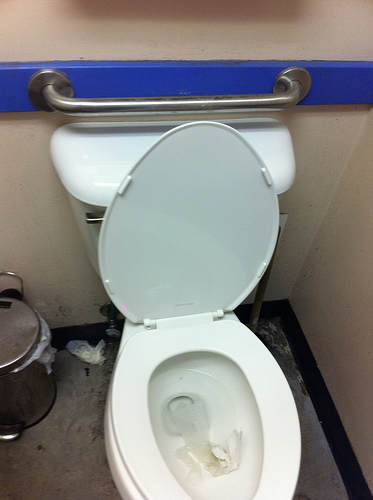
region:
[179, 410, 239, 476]
tissue in the toilet bowl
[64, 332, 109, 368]
paper on a dirty floor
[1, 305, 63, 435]
silver trash can near a toilet bowl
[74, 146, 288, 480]
toilet bowl with its seat up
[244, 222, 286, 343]
Plunger near a toilet bowl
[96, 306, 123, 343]
silver knob on the wall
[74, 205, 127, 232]
Chrome handle on a toilet bowl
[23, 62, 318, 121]
Hand bar over the towel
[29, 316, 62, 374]
Trash bag in a silver can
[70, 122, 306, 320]
white lid on a toilet seat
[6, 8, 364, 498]
a toilet is in a bathroom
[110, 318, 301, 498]
the seat is down on the toilet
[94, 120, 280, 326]
the lid of the toilet is up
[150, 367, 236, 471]
water is in the bowl of the toilet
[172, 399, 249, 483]
paper is in the bowl of the toilet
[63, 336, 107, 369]
paper is on the floor of the bathroom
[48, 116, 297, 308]
the water closet is behind the lid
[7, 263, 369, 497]
the floor of the bathroom is dirty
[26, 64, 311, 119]
a chrome grab bar is over the toilet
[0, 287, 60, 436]
a stainless steel trash can is in theroom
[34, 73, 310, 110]
metal bar above toilet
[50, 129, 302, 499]
white toilet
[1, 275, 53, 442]
metal trash can on floor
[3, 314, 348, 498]
gray concrete floor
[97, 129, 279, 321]
toilet seat cover is up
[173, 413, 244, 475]
toilet paper in toilet bowl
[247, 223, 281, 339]
plunger beside the toilet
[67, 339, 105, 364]
wad of paper on the ground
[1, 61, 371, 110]
blue piece of wood on the wall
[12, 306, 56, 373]
plastic trash bag in can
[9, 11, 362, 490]
a toilet in a bathroom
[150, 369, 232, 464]
clear water is in the toilet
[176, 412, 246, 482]
toilet paper is in the bowl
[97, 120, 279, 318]
the lid is up on the toilet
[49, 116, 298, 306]
the water tank is behind the lid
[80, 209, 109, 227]
a chrome handle is on the toilet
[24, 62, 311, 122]
a grab bar is above the toilet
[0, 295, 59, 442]
a chrome trash can is in the bathroom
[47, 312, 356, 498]
the floor of the bathroom is filthy